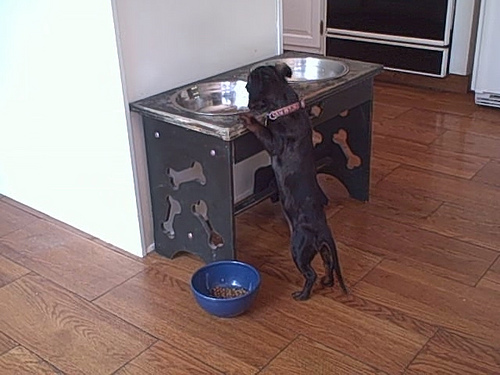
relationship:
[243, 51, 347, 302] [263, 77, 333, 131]
dog has collar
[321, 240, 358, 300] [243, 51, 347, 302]
tail of dog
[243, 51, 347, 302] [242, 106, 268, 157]
dog has arm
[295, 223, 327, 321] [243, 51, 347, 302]
leg of dog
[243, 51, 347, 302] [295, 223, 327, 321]
dog has leg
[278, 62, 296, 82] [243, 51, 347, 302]
ear of dog